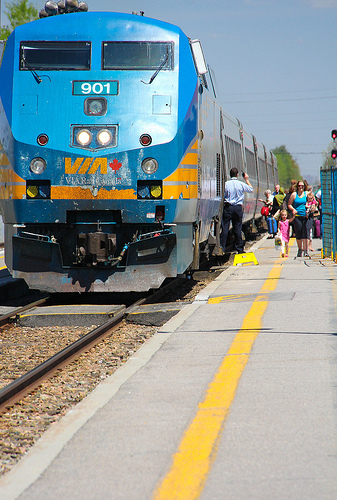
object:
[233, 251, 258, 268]
stool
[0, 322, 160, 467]
gravel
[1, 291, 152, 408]
track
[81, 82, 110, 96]
901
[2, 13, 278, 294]
train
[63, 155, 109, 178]
via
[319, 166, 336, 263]
fence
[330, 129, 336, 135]
light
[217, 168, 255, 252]
conductor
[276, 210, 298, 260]
girl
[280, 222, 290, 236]
pink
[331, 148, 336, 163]
lights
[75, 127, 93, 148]
light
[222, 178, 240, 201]
blue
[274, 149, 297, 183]
tree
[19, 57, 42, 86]
wipers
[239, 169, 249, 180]
walkie-talkie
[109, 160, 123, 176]
leaf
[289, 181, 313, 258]
woman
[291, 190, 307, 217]
tank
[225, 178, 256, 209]
shirt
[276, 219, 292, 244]
shirt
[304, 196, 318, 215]
baby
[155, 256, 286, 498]
line